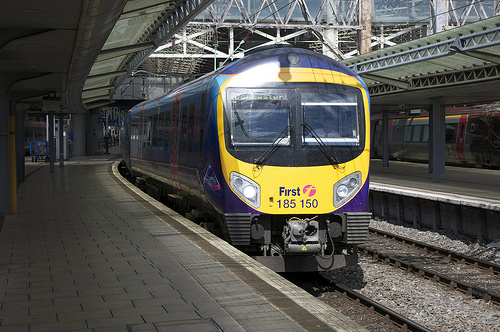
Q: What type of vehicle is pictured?
A: A train.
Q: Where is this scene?
A: A train station.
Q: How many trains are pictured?
A: Two.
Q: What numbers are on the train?
A: 185150.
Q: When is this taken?
A: Daytime.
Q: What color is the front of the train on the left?
A: Yellow.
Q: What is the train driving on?
A: Train tracks.